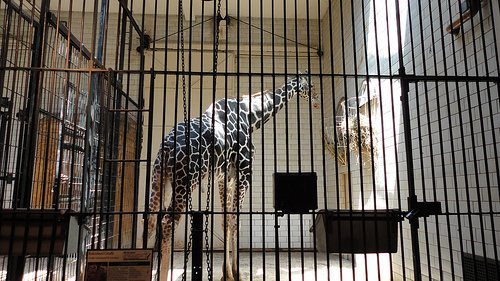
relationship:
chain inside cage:
[204, 2, 218, 278] [16, 3, 484, 277]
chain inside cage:
[179, 5, 193, 280] [16, 3, 484, 277]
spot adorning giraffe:
[218, 139, 230, 152] [142, 66, 321, 279]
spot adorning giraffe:
[152, 159, 160, 166] [142, 66, 321, 279]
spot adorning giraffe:
[168, 144, 180, 158] [142, 66, 321, 279]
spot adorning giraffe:
[181, 143, 193, 155] [142, 66, 321, 279]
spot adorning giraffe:
[252, 103, 264, 119] [142, 66, 321, 279]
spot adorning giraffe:
[238, 159, 250, 169] [142, 66, 321, 279]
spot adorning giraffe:
[239, 146, 250, 162] [142, 66, 321, 279]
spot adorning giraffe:
[231, 130, 248, 146] [142, 66, 321, 279]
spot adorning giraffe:
[213, 120, 226, 137] [142, 66, 321, 279]